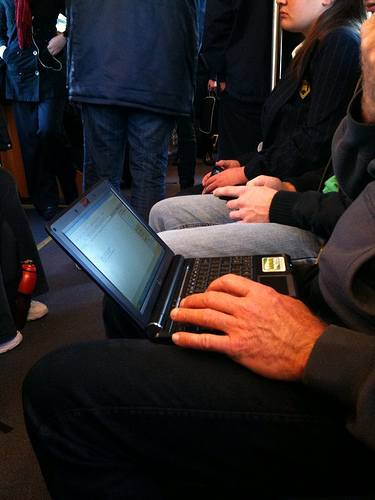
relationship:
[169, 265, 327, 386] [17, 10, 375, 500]
hand of man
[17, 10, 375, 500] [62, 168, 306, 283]
man using laptop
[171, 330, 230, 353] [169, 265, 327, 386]
finger on hand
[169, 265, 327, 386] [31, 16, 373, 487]
hand of man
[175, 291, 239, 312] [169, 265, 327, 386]
finger on hand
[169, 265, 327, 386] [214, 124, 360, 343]
hand of man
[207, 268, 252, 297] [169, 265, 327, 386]
finger on hand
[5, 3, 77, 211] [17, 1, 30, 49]
person wearing red scarf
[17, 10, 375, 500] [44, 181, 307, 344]
man using netbook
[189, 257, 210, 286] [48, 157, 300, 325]
key on laptop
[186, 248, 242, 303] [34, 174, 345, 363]
key on laptop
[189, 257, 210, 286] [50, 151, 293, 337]
key on laptop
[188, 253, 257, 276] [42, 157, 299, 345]
black key on laptop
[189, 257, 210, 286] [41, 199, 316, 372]
key on laptop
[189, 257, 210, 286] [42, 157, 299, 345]
key on laptop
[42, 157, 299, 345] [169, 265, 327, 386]
laptop in a hand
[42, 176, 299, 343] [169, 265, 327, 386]
lap top in a hand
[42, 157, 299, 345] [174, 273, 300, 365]
laptop in a man's hand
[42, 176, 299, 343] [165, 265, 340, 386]
lap top in a hand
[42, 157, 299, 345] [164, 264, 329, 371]
laptop in a hand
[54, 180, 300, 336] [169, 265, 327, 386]
lap top in a hand